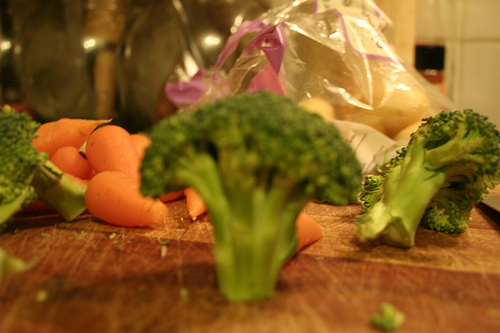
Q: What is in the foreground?
A: Broccoli.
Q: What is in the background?
A: Carrot.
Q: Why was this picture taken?
A: Perspective.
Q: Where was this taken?
A: Kitchen.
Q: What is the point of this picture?
A: Art.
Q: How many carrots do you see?
A: Over two.